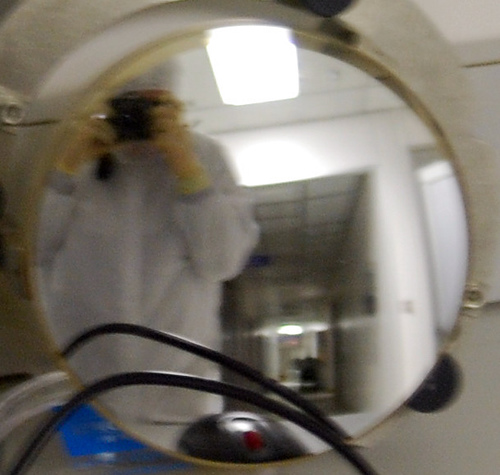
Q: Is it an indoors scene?
A: Yes, it is indoors.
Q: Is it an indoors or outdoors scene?
A: It is indoors.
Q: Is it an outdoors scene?
A: No, it is indoors.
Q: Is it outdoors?
A: No, it is indoors.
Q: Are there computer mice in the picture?
A: Yes, there is a computer mouse.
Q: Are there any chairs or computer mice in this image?
A: Yes, there is a computer mouse.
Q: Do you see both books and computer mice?
A: No, there is a computer mouse but no books.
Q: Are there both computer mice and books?
A: No, there is a computer mouse but no books.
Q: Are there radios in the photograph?
A: No, there are no radios.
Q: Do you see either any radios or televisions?
A: No, there are no radios or televisions.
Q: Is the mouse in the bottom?
A: Yes, the mouse is in the bottom of the image.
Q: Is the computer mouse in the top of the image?
A: No, the computer mouse is in the bottom of the image.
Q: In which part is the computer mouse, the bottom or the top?
A: The computer mouse is in the bottom of the image.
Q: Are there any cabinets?
A: No, there are no cabinets.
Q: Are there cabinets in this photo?
A: No, there are no cabinets.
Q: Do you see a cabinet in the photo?
A: No, there are no cabinets.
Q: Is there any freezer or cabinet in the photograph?
A: No, there are no cabinets or refrigerators.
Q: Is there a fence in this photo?
A: No, there are no fences.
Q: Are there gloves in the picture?
A: Yes, there are gloves.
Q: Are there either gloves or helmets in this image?
A: Yes, there are gloves.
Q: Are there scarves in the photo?
A: No, there are no scarves.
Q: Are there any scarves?
A: No, there are no scarves.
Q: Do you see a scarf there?
A: No, there are no scarves.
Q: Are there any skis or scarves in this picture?
A: No, there are no scarves or skis.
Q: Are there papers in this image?
A: No, there are no papers.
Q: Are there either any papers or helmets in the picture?
A: No, there are no papers or helmets.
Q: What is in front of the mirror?
A: The wire is in front of the mirror.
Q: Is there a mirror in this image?
A: Yes, there is a mirror.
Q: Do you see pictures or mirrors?
A: Yes, there is a mirror.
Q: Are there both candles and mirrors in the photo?
A: No, there is a mirror but no candles.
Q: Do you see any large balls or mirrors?
A: Yes, there is a large mirror.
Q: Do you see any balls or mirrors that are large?
A: Yes, the mirror is large.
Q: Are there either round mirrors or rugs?
A: Yes, there is a round mirror.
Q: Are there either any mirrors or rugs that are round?
A: Yes, the mirror is round.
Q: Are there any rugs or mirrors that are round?
A: Yes, the mirror is round.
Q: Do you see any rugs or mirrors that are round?
A: Yes, the mirror is round.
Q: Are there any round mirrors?
A: Yes, there is a round mirror.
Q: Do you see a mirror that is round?
A: Yes, there is a mirror that is round.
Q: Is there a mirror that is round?
A: Yes, there is a mirror that is round.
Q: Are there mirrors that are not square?
A: Yes, there is a round mirror.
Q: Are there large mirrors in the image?
A: Yes, there is a large mirror.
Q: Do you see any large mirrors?
A: Yes, there is a large mirror.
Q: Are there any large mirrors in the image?
A: Yes, there is a large mirror.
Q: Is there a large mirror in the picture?
A: Yes, there is a large mirror.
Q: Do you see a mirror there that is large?
A: Yes, there is a mirror that is large.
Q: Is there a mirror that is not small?
A: Yes, there is a large mirror.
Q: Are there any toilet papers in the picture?
A: No, there are no toilet papers.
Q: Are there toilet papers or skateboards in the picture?
A: No, there are no toilet papers or skateboards.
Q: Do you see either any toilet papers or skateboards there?
A: No, there are no toilet papers or skateboards.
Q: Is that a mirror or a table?
A: That is a mirror.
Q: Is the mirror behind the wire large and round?
A: Yes, the mirror is large and round.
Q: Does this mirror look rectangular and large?
A: No, the mirror is large but round.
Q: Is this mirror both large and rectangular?
A: No, the mirror is large but round.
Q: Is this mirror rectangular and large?
A: No, the mirror is large but round.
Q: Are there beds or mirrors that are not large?
A: No, there is a mirror but it is large.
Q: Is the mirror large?
A: Yes, the mirror is large.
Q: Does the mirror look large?
A: Yes, the mirror is large.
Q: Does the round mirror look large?
A: Yes, the mirror is large.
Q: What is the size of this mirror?
A: The mirror is large.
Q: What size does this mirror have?
A: The mirror has large size.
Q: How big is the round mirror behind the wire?
A: The mirror is large.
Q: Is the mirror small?
A: No, the mirror is large.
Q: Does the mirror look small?
A: No, the mirror is large.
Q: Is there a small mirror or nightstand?
A: No, there is a mirror but it is large.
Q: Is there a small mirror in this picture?
A: No, there is a mirror but it is large.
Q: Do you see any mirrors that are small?
A: No, there is a mirror but it is large.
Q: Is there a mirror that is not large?
A: No, there is a mirror but it is large.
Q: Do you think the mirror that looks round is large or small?
A: The mirror is large.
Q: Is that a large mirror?
A: Yes, that is a large mirror.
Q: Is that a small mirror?
A: No, that is a large mirror.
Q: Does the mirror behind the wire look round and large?
A: Yes, the mirror is round and large.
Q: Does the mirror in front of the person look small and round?
A: No, the mirror is round but large.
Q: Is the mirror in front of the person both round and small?
A: No, the mirror is round but large.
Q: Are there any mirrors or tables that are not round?
A: No, there is a mirror but it is round.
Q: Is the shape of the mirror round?
A: Yes, the mirror is round.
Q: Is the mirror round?
A: Yes, the mirror is round.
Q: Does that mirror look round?
A: Yes, the mirror is round.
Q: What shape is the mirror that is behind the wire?
A: The mirror is round.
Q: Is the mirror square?
A: No, the mirror is round.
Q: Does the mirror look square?
A: No, the mirror is round.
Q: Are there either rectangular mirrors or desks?
A: No, there is a mirror but it is round.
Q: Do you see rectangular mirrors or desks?
A: No, there is a mirror but it is round.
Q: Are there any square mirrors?
A: No, there is a mirror but it is round.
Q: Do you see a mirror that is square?
A: No, there is a mirror but it is round.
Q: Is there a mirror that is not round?
A: No, there is a mirror but it is round.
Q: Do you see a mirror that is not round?
A: No, there is a mirror but it is round.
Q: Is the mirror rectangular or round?
A: The mirror is round.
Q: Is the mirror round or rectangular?
A: The mirror is round.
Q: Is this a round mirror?
A: Yes, this is a round mirror.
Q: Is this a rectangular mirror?
A: No, this is a round mirror.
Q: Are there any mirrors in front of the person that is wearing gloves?
A: Yes, there is a mirror in front of the person.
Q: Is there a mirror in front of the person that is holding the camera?
A: Yes, there is a mirror in front of the person.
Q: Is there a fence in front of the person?
A: No, there is a mirror in front of the person.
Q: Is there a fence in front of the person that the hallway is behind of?
A: No, there is a mirror in front of the person.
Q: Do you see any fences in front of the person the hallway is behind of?
A: No, there is a mirror in front of the person.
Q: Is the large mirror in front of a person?
A: Yes, the mirror is in front of a person.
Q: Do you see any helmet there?
A: No, there are no helmets.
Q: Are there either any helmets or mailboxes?
A: No, there are no helmets or mailboxes.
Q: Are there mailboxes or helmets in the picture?
A: No, there are no helmets or mailboxes.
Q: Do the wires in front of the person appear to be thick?
A: Yes, the wires are thick.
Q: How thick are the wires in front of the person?
A: The wires are thick.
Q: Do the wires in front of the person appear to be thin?
A: No, the wires are thick.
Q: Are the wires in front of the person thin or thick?
A: The wires are thick.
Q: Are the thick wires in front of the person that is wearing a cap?
A: Yes, the wires are in front of the person.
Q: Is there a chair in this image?
A: No, there are no chairs.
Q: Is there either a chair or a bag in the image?
A: No, there are no chairs or bags.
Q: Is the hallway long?
A: Yes, the hallway is long.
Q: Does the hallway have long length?
A: Yes, the hallway is long.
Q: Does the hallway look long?
A: Yes, the hallway is long.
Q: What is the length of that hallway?
A: The hallway is long.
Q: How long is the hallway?
A: The hallway is long.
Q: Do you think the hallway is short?
A: No, the hallway is long.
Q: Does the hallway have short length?
A: No, the hallway is long.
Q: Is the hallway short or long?
A: The hallway is long.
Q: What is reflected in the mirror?
A: The hallway is reflected in the mirror.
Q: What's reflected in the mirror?
A: The hallway is reflected in the mirror.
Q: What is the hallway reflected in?
A: The hallway is reflected in the mirror.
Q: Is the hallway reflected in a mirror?
A: Yes, the hallway is reflected in a mirror.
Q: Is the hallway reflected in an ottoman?
A: No, the hallway is reflected in a mirror.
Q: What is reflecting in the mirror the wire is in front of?
A: The hallway is reflecting in the mirror.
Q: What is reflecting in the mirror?
A: The hallway is reflecting in the mirror.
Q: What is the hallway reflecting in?
A: The hallway is reflecting in the mirror.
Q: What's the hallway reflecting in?
A: The hallway is reflecting in the mirror.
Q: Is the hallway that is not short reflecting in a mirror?
A: Yes, the hallway is reflecting in a mirror.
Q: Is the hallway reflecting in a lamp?
A: No, the hallway is reflecting in a mirror.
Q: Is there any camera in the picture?
A: Yes, there is a camera.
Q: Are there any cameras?
A: Yes, there is a camera.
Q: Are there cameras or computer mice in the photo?
A: Yes, there is a camera.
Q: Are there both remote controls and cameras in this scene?
A: No, there is a camera but no remote controls.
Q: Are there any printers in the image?
A: No, there are no printers.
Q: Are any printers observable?
A: No, there are no printers.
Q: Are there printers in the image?
A: No, there are no printers.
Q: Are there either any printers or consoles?
A: No, there are no printers or consoles.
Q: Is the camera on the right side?
A: No, the camera is on the left of the image.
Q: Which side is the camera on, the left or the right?
A: The camera is on the left of the image.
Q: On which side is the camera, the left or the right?
A: The camera is on the left of the image.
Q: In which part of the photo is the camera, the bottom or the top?
A: The camera is in the top of the image.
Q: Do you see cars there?
A: No, there are no cars.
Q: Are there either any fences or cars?
A: No, there are no cars or fences.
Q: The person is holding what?
A: The person is holding the camera.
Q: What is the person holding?
A: The person is holding the camera.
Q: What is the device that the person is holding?
A: The device is a camera.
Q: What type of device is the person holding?
A: The person is holding the camera.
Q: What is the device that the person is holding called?
A: The device is a camera.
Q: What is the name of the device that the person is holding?
A: The device is a camera.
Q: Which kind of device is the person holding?
A: The person is holding the camera.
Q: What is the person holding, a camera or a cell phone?
A: The person is holding a camera.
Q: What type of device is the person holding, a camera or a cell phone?
A: The person is holding a camera.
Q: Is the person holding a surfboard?
A: No, the person is holding the camera.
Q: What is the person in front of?
A: The person is in front of the hallway.